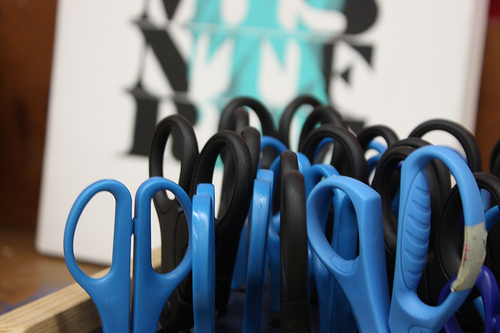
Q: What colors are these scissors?
A: Blue and black.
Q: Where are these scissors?
A: In a wooden box.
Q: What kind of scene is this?
A: Indoor.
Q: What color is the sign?
A: White.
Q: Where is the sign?
A: Behind the scissors.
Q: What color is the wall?
A: Brown.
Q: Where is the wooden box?
A: On a surface.